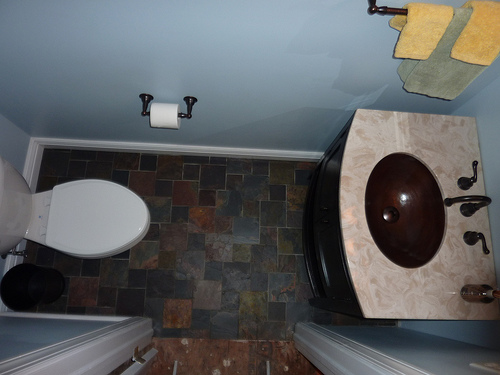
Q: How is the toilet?
A: White.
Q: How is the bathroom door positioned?
A: Open.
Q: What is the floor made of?
A: Tiles.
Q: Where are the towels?
A: On the towel rack.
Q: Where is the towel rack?
A: On the bathroom wall.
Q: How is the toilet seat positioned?
A: Down.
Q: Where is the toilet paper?
A: Hanging on bathroom wall.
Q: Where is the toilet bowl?
A: In the bathroom.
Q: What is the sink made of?
A: Porcelain.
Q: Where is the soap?
A: On the sink counter.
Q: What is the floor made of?
A: Tiles.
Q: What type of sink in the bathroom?
A: Oval sink.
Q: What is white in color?
A: Toilet.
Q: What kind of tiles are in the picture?
A: Multi colored tiles.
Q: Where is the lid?
A: Above the toilet.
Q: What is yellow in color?
A: A hand cloth.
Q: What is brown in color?
A: The sink.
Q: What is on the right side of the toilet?
A: Tissue paper.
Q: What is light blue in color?
A: Wall.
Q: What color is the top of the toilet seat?
A: White.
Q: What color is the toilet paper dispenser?
A: Black.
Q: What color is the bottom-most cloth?
A: Green.